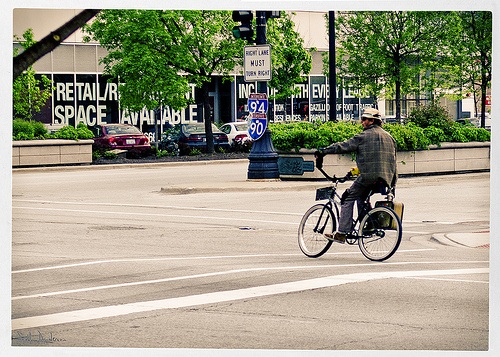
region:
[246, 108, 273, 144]
the sign for interstate 90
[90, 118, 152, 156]
the red parked car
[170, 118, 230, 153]
the blue parked car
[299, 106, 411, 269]
man riding a bike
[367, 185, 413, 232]
the yellow suitcase in the man's hand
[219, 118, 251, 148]
the white parked car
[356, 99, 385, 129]
the white hat on the man's head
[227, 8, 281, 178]
the traffic light with signs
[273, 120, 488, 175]
the plants on the median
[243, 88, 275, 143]
red, white, and blue interstate signs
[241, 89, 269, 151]
interstate street signs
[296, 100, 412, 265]
a man on a bicycle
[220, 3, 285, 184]
a traffic stoplight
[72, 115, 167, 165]
a parked red car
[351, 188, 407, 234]
a yellow and black briefcase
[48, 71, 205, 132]
a painted window advertisement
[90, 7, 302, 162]
a green tree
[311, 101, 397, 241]
a man wearing a coat and hat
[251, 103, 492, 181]
a median greenspace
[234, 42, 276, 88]
a right turn directional sign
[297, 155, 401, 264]
black bicycle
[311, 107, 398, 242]
Guy with white hat on the bicycle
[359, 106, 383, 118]
white hat with feather on man's head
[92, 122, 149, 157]
red car in parking lot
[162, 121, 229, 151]
blue car in parking lot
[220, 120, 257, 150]
white car in parking lot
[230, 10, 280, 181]
Traffic light with signs on them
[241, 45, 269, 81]
white sign on traffic light post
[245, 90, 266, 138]
blue signs on traffic light post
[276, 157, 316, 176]
sign on the wall beside the traffic light post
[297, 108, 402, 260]
man riding bicycle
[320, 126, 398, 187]
gray plaid jacket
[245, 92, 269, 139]
blue and red highway signs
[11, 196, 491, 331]
white lines on street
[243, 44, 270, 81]
white directional street sign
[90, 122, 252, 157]
row of parked cars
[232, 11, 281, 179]
blue traffic light pole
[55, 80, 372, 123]
building with paint on windows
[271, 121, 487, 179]
median filled with greenery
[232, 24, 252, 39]
green traffic light signal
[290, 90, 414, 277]
Man riding a bike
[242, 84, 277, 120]
Blue and white sign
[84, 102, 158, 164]
Red compact car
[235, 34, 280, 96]
White sign with black writing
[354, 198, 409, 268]
Black and white bicycle tire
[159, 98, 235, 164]
Small blue car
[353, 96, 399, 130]
White hat with feather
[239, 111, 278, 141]
Red, white and blue sign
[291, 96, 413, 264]
Person riding a bike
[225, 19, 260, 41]
Green stop light